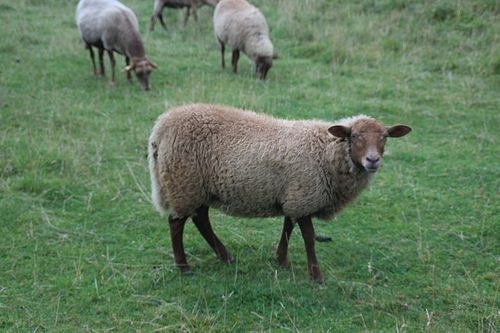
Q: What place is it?
A: It is a pasture.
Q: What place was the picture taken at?
A: It was taken at the pasture.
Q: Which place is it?
A: It is a pasture.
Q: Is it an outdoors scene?
A: Yes, it is outdoors.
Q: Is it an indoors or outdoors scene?
A: It is outdoors.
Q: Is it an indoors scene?
A: No, it is outdoors.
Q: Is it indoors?
A: No, it is outdoors.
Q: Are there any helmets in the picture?
A: No, there are no helmets.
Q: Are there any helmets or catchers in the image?
A: No, there are no helmets or catchers.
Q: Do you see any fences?
A: No, there are no fences.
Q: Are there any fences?
A: No, there are no fences.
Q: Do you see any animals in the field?
A: Yes, there is an animal in the field.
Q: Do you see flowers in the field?
A: No, there is an animal in the field.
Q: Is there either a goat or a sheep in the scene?
A: Yes, there is a sheep.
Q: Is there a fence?
A: No, there are no fences.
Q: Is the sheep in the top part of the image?
A: Yes, the sheep is in the top of the image.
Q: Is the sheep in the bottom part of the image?
A: No, the sheep is in the top of the image.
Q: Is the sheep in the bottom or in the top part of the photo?
A: The sheep is in the top of the image.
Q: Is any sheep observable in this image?
A: Yes, there is a sheep.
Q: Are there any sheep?
A: Yes, there is a sheep.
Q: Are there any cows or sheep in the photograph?
A: Yes, there is a sheep.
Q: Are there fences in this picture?
A: No, there are no fences.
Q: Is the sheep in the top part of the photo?
A: Yes, the sheep is in the top of the image.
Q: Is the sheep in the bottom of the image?
A: No, the sheep is in the top of the image.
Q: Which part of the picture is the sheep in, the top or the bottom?
A: The sheep is in the top of the image.